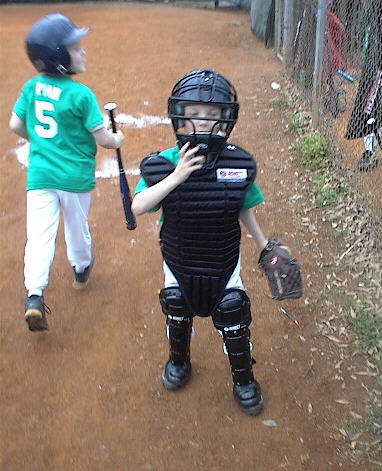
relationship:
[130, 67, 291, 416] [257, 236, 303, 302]
boy has catchers mitt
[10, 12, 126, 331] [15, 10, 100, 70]
boy has helmet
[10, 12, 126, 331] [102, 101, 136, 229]
boy holding bat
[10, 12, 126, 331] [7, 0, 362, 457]
boy on field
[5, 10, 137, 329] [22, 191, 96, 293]
boy wearing white pants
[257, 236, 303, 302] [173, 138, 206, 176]
catchers mitt on hand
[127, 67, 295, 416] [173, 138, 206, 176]
boy has hand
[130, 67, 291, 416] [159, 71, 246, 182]
boy has helmet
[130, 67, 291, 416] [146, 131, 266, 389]
boy has catcher's outfit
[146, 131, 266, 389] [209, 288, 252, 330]
catcher's outfit has knee pad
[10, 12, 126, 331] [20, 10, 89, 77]
boy wearing batter's helmet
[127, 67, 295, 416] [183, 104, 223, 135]
boy has face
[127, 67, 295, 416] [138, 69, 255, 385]
boy wearing gear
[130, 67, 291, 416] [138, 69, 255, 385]
boy wearing gear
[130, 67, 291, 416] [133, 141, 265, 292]
boy wearing uniform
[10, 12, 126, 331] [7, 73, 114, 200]
boy wearing uniform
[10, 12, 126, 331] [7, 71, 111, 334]
boy wearing uniform